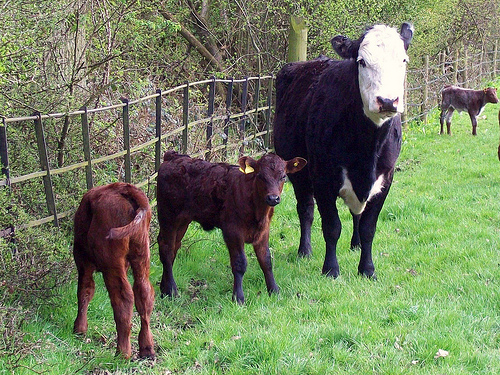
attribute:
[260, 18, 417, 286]
cow — black, white, standing, adult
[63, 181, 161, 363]
cow — red, baby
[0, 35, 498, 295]
fence — wood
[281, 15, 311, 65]
fence post — wood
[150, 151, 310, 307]
calf — brown, dark brown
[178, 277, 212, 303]
grass — dead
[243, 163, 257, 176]
tag — yellow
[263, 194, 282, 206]
nose — black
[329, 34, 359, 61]
ear — black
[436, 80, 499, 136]
calf — in the distance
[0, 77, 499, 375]
field — grassy